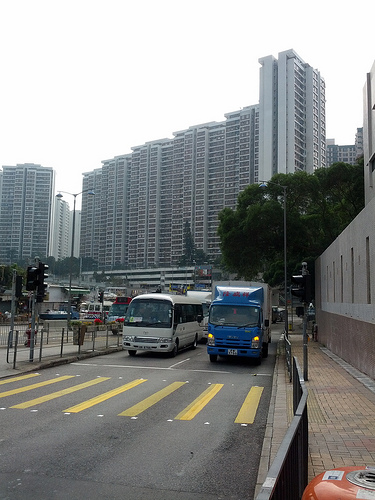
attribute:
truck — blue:
[209, 280, 272, 368]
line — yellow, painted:
[232, 382, 264, 424]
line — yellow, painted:
[175, 381, 224, 422]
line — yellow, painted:
[120, 379, 186, 417]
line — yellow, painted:
[63, 377, 146, 416]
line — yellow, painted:
[11, 376, 107, 412]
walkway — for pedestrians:
[1, 371, 273, 426]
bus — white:
[119, 293, 205, 355]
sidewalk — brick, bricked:
[287, 332, 375, 482]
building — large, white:
[78, 50, 326, 289]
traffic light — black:
[25, 262, 50, 303]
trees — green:
[215, 153, 363, 285]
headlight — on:
[253, 337, 260, 350]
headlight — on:
[208, 334, 215, 344]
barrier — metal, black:
[256, 332, 307, 500]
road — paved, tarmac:
[1, 303, 306, 499]